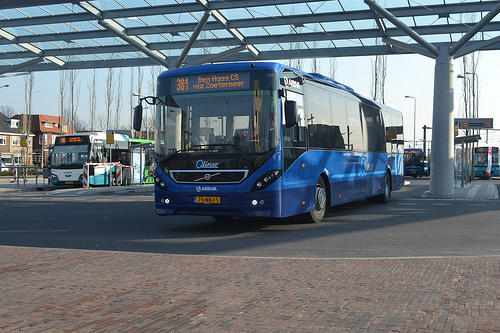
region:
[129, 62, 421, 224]
blue bus at bus station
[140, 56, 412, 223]
blue and black bus at bus station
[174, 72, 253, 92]
yellow destination sign on bus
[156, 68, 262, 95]
yellow destination sign on bus at bus station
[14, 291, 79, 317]
brown and gray bricks in street pavement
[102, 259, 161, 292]
brown and gray bricks in street pavement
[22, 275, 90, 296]
brown and gray bricks in street pavement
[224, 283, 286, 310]
brown and gray bricks in street pavement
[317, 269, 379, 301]
brown and gray bricks in street pavement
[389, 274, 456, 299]
brown and gray bricks in street pavement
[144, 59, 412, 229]
the bus is blue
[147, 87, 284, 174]
the bus has a windshield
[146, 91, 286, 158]
the windshield is large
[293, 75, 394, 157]
the bus has many windows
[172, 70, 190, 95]
the bus has a number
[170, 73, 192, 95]
the number is 381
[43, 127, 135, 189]
the bus is blue and white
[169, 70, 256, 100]
the sign on the bus is digital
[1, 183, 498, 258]
the shadow is on the ground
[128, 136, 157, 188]
the bus stop is green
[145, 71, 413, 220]
Blue bus with windows.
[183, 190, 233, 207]
Orange license plate on bus.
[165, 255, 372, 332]
Cobblestone brick pavement.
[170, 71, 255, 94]
Orange numbers and letters on bus sign.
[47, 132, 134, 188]
White and green bus.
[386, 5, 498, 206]
Large cement pole in bus station.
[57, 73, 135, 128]
Skinny trees with no leaves.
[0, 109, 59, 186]
Two homes in the background to the left.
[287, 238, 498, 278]
Dividing line between pavement and brick cobblestone.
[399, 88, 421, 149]
Street light.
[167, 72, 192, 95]
384 on front of bus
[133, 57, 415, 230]
blue bus parked under awning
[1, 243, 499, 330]
sidewalk made of bricks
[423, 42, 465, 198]
column holding up awning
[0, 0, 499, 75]
awning over busses is glass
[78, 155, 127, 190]
barrier beside parked bus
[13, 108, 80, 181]
house parked beside sidewalk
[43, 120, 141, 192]
bus parked by sidewalk is white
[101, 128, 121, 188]
yellow sign beside barricade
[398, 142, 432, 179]
bus behind blue bus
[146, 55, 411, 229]
blue transit bus at bus station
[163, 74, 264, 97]
yellow destination sign on blue bus at station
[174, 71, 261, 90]
yellow destination sign on blue bus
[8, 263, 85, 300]
gray and tan bricks in street pavement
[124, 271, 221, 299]
gray and tan bricks in street pavement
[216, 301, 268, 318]
gray and tan bricks in street pavement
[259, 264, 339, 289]
gray and tan bricks in street pavement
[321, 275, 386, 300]
gray and tan bricks in street pavement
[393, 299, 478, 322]
gray and tan bricks in street pavement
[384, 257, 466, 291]
gray and tan bricks in street pavement